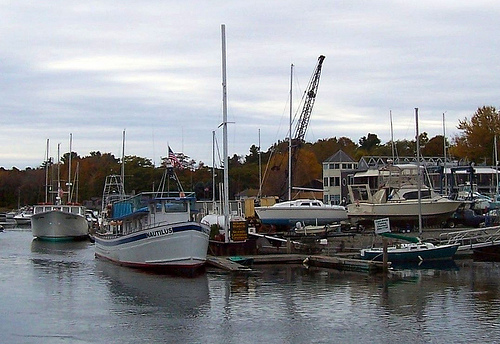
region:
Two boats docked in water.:
[28, 134, 211, 295]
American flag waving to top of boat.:
[159, 138, 189, 168]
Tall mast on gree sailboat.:
[406, 103, 429, 245]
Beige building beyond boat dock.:
[320, 146, 463, 201]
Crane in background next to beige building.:
[266, 50, 324, 207]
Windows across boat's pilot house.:
[28, 198, 87, 218]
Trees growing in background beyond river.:
[1, 148, 156, 217]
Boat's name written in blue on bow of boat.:
[134, 221, 182, 248]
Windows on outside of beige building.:
[321, 163, 344, 195]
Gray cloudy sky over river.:
[16, 19, 201, 127]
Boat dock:
[210, 252, 395, 290]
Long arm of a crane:
[255, 32, 345, 199]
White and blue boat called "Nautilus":
[82, 157, 226, 287]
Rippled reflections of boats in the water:
[90, 256, 499, 329]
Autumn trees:
[0, 130, 499, 200]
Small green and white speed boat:
[357, 225, 462, 270]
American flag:
[161, 139, 183, 169]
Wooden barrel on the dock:
[227, 216, 252, 246]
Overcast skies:
[9, 4, 449, 149]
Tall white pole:
[211, 19, 237, 249]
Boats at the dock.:
[12, 117, 488, 278]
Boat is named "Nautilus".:
[135, 220, 180, 243]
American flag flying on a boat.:
[162, 140, 182, 171]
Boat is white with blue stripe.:
[85, 220, 215, 266]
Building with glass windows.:
[320, 145, 346, 200]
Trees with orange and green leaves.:
[1, 130, 496, 195]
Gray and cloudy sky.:
[5, 5, 495, 97]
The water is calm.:
[2, 280, 492, 335]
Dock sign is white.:
[370, 210, 391, 275]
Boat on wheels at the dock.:
[343, 160, 459, 232]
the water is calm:
[44, 268, 196, 327]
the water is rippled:
[49, 253, 127, 323]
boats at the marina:
[203, 242, 486, 283]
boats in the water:
[8, 179, 225, 292]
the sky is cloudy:
[34, 23, 189, 108]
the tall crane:
[257, 32, 329, 208]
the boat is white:
[86, 190, 218, 273]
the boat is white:
[23, 177, 88, 241]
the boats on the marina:
[243, 180, 461, 232]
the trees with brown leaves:
[248, 137, 326, 184]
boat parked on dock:
[92, 192, 213, 274]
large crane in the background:
[257, 50, 325, 192]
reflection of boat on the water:
[96, 255, 207, 321]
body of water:
[1, 225, 499, 342]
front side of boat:
[29, 206, 93, 242]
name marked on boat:
[145, 222, 175, 232]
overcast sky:
[0, 1, 499, 168]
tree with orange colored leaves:
[453, 105, 499, 162]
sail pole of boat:
[219, 19, 229, 262]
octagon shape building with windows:
[319, 148, 354, 205]